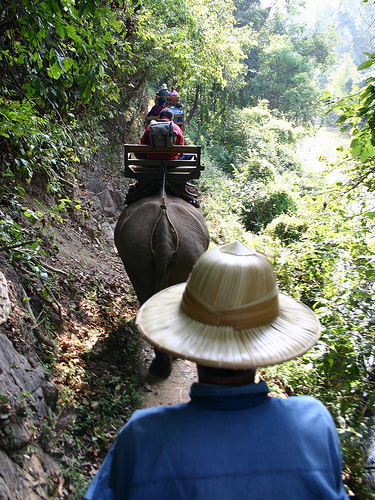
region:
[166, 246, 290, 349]
this is a hat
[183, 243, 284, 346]
the hat is brown in color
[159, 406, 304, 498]
the t shirt is blue in color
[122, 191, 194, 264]
this is an elephant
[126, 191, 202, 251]
the elephant is in front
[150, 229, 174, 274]
this is the tail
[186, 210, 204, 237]
this is the belly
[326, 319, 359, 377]
the leaves are green in color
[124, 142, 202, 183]
tis is a seat in front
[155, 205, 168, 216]
this is s arope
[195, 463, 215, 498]
part of a shirt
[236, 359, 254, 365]
edge of a hat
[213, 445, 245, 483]
part of a shirt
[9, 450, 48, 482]
part of a stone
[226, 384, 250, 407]
part of a collar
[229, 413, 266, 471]
part of a short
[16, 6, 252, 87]
these are some trees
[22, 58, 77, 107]
the leaves are green in color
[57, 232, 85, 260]
this is the ground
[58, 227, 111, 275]
the ground is sandy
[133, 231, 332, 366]
this is a hat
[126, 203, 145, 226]
the fur is grey in color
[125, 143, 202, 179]
this is a bench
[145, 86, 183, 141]
these are some people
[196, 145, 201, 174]
the bench is wooden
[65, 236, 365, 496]
Person is in the foreground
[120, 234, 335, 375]
Person is wearing a hat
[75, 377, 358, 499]
Person is wearing a blue shirt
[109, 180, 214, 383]
An elephant in the background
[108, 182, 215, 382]
A back view of an elephant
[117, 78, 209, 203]
People on top of a elephant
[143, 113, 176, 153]
Person is wearing a backpack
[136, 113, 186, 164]
Person is wearing a red shirt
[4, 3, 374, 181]
Tall trees in the background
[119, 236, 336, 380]
Straw hat is tan colored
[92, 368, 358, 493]
Man wearing a blue shirt.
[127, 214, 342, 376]
The hat is made of straw.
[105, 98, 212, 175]
Man riding on an elephant.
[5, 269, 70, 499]
Rocks along the path.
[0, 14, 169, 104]
Green foliage along the path.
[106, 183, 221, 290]
Back end of an elephant.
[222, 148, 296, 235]
Green plants in the jungle.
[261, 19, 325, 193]
Sunlight shining in the jungle.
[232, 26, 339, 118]
Green trees in the distance.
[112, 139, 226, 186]
A bench made for riding an elephant.